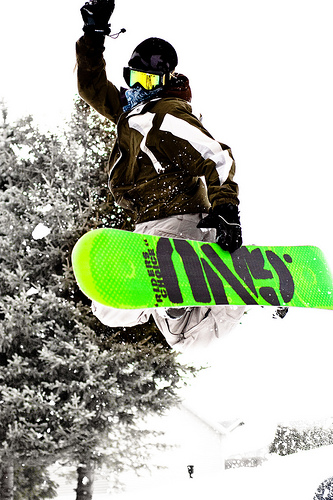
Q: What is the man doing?
A: Snowboarding.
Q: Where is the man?
A: In the air.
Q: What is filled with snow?
A: The trees.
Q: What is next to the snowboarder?
A: Trees.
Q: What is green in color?
A: Snowboard.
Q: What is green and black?
A: The board.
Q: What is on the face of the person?
A: Goggles.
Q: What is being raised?
A: Man's arm.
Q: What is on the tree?
A: Snow.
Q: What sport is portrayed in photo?
A: Snowboarding.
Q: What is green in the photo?
A: Snowboard.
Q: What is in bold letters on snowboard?
A: GNU.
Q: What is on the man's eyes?
A: Goggles.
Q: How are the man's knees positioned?
A: Bent upwards.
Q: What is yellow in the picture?
A: Board.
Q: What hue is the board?
A: Yellow.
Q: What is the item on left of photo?
A: Tree.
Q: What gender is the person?
A: A man.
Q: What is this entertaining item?
A: Snowboard.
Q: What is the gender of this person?
A: A man.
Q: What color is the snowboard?
A: Green.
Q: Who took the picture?
A: Photographer.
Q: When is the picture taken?
A: Daytime.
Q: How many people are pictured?
A: One.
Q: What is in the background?
A: Tree.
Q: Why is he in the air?
A: Ramped.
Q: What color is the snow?
A: White.